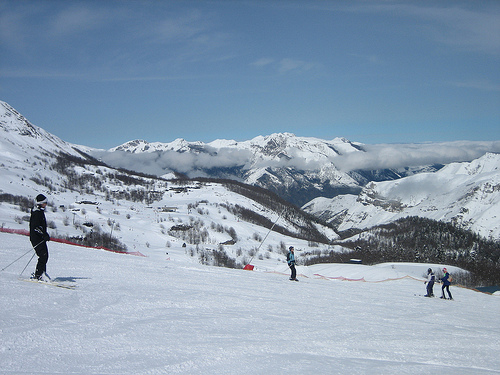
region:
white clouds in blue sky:
[37, 11, 114, 56]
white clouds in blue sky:
[258, 19, 389, 89]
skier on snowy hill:
[5, 189, 76, 279]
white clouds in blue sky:
[275, 5, 320, 59]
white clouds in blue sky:
[411, 52, 452, 87]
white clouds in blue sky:
[192, 66, 230, 110]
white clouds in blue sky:
[260, 51, 320, 96]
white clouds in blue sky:
[45, 19, 180, 89]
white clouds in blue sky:
[104, 0, 142, 45]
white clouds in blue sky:
[137, 59, 174, 93]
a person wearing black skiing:
[7, 184, 80, 292]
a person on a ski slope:
[282, 239, 305, 288]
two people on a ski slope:
[417, 261, 459, 307]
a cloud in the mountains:
[341, 132, 488, 176]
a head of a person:
[30, 193, 51, 213]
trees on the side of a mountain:
[81, 164, 163, 204]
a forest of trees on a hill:
[379, 216, 462, 262]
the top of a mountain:
[245, 126, 332, 151]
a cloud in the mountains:
[99, 144, 261, 179]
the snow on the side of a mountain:
[5, 123, 57, 158]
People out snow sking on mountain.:
[276, 241, 456, 303]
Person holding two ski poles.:
[0, 230, 55, 279]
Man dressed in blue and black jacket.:
[282, 251, 302, 267]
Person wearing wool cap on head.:
[27, 188, 52, 207]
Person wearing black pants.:
[22, 237, 52, 276]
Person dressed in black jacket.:
[25, 205, 54, 245]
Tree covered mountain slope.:
[221, 174, 326, 241]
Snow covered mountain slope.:
[402, 168, 465, 217]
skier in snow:
[14, 192, 76, 286]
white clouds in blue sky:
[307, 45, 365, 99]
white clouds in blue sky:
[405, 8, 472, 72]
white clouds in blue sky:
[198, 11, 276, 65]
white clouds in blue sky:
[158, 55, 213, 96]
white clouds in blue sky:
[108, 31, 172, 82]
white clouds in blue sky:
[85, 51, 133, 96]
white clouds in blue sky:
[207, 28, 249, 79]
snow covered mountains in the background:
[1, 99, 498, 278]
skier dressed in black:
[6, 183, 83, 294]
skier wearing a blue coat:
[274, 239, 304, 286]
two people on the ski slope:
[415, 260, 460, 300]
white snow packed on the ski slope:
[0, 231, 497, 373]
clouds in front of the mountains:
[83, 136, 497, 179]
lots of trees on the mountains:
[4, 144, 489, 296]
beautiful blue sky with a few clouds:
[3, 2, 499, 138]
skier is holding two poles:
[1, 185, 76, 295]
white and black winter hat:
[31, 190, 51, 206]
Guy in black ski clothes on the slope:
[1, 193, 80, 289]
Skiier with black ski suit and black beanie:
[4, 190, 75, 289]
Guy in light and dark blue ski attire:
[273, 244, 307, 281]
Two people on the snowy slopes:
[421, 268, 458, 302]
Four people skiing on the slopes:
[8, 189, 463, 300]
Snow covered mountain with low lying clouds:
[70, 113, 484, 200]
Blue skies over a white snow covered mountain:
[49, 68, 481, 174]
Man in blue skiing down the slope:
[282, 235, 307, 283]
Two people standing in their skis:
[417, 263, 462, 303]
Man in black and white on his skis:
[7, 193, 83, 289]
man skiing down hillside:
[4, 194, 84, 291]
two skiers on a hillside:
[421, 265, 457, 301]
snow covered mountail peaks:
[213, 127, 363, 197]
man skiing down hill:
[279, 243, 304, 281]